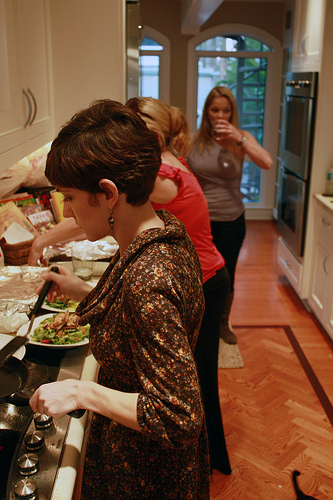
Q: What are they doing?
A: Cooking.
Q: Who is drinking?
A: The blond woman in the brown shirt.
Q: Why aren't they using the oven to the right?
A: Don't need it.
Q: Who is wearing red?
A: Woman in the middle.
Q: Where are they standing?
A: Kitchen.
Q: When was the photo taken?
A: Dinner time.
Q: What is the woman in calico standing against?
A: A stove.